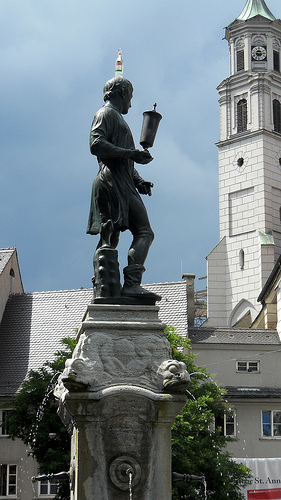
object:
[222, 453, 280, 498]
sign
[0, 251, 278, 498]
building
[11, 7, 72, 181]
sky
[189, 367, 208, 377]
water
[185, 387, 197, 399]
water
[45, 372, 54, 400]
water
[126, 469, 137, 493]
water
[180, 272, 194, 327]
chimney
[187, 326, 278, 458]
building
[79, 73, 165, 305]
statue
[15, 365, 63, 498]
water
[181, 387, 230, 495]
water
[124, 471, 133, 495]
water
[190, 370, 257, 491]
water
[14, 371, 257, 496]
places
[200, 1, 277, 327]
tower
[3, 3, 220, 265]
sky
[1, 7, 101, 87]
clouds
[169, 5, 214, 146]
clouds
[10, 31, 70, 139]
clouds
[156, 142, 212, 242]
clouds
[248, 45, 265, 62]
clock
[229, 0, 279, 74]
tower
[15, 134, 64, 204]
yellow leaves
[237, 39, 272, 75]
clock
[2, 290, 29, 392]
shadow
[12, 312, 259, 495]
tree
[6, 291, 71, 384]
roof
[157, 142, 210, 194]
clouds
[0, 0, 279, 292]
blue sky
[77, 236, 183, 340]
water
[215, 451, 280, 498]
banner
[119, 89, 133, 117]
face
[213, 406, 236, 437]
window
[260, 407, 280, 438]
window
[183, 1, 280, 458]
building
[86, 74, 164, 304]
statue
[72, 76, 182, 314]
statue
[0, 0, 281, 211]
clouds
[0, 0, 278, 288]
clouds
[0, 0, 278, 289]
sky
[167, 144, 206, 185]
white clouds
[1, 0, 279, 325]
blue sky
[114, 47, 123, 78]
bottle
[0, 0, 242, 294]
clouds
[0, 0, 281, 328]
sky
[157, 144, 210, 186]
white clouds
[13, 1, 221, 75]
blue sky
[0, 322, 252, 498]
tree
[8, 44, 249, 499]
fountain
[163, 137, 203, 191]
white clouds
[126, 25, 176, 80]
blue sky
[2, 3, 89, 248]
sky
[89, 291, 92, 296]
shingle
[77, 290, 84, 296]
shingle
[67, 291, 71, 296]
shingle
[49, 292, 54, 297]
shingle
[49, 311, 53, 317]
shingle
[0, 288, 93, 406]
roof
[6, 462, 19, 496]
window frame